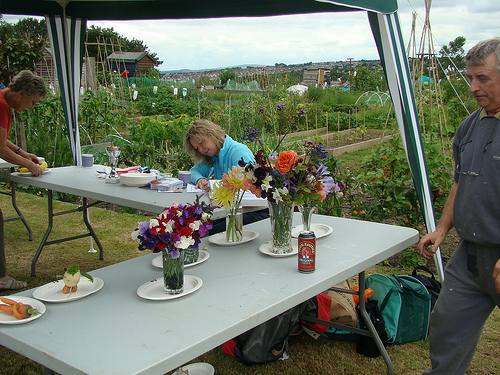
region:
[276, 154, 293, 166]
the flower is orange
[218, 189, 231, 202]
the flower is yellow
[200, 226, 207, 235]
the flower is dark purple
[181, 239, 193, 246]
the flower is white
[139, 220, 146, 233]
the flower is light purple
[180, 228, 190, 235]
the flower is red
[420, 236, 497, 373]
Man wearing pants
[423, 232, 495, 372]
Man is wearing pants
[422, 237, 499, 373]
Man wearing gray pants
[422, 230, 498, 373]
Man is wearing gray pants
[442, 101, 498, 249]
Man wearing a shirt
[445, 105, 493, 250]
Man is wearing a shirt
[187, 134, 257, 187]
Woman wearing a shirt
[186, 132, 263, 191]
Woman is wearing a shirt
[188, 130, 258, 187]
Woman wearing a light blue shirt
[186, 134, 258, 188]
Woman is wearing a light blue shirt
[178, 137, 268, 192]
A light blue jacket on the blonde woman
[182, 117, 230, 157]
Long blonde hair on the woman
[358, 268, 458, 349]
A large green bag on the ground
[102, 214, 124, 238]
Short green grass grows on the ground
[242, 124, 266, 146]
Small purple flowers by the woman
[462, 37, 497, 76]
The old man has short grey hair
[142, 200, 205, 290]
A bouquet of flowers on the table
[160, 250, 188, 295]
A glass vase on the plate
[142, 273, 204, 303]
A white plate beneath the vase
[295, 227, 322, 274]
A red and green aluminum can on the table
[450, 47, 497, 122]
the head of a man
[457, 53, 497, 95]
the eye of a man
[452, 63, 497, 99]
the nose of a man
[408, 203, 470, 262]
the hand of a man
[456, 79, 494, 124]
the chin of a man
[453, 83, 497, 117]
the mouth of a man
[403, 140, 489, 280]
the arm of a man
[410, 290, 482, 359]
the knee of a man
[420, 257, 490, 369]
the leg of a man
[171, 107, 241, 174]
the head of a woman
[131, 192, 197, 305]
flowers in a vase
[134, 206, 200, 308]
flowers in a vase on the table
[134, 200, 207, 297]
flowers in a clear vase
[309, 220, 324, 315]
a can of drink on the table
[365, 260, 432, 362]
a green bag on the grass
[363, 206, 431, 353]
a green bag under the table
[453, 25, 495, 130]
part of a man's face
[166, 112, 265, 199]
a lady with curly hair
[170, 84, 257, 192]
a lady with curly hair sitting down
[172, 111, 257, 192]
a woman writing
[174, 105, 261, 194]
a woman in a blue jacket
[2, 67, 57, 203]
man in a red shirt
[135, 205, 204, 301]
white red and purple flowers in a glass on a plate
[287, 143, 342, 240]
flowers in a glass on a plate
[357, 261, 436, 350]
a blue pack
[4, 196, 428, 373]
a grey table with food on it and packs under it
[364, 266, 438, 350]
a large green and black duffel bag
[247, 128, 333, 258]
a bouquet of colorful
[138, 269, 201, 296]
a white paper plate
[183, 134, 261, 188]
a woman's blue jacket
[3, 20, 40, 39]
green trees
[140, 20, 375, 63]
a long white cloud